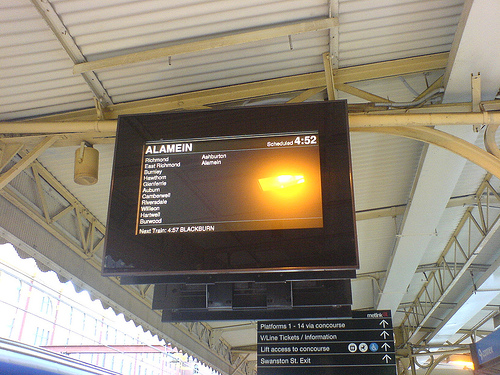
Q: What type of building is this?
A: An airport.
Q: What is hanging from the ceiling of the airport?
A: A television.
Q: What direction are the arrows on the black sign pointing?
A: Up.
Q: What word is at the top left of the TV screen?
A: Alamein.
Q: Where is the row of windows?
A: On the left of the picture.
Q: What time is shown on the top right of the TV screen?
A: 4:52.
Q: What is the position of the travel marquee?
A: Overhead.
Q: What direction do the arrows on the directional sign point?
A: Up which means straight ahead.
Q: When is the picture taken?
A: 4:52.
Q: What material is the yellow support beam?
A: Steel.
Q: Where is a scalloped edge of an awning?
A: Left of the area.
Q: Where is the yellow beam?
A: Ceiling.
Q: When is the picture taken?
A: Daytime.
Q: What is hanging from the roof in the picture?
A: Computer screens and signs.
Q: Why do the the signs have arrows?
A: Show which way to go.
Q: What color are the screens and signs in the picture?
A: Black.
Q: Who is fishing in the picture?
A: No one.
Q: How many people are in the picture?
A: None.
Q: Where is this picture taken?
A: Transportation depot.